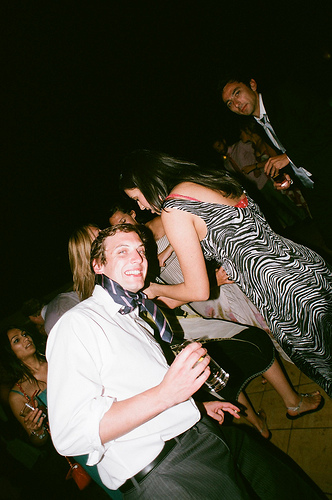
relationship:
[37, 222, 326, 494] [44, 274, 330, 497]
boy wearing suit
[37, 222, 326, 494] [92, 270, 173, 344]
boy wearing tie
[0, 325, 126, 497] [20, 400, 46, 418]
girl holding cocktail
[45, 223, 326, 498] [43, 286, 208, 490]
boy wearing shirt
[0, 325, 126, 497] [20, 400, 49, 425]
girl holding cocktail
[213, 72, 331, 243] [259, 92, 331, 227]
man wearing suit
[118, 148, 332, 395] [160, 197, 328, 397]
girl wearing dress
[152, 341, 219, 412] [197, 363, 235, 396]
hand holding glass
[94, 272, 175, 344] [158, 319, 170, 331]
tie with stripes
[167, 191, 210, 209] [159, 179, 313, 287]
bra displayed by woman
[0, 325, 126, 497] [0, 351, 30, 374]
girl with hair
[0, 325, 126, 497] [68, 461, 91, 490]
girl with bag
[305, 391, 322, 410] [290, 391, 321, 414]
foot in sandal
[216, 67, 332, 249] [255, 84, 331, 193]
man wears suit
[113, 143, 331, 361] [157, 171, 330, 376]
girl wears dress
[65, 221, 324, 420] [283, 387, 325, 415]
girl wears sandals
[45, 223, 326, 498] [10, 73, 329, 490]
boy in crowd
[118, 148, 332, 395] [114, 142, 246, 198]
girl has hair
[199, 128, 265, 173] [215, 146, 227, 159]
man has beard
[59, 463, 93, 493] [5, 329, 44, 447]
bag with woman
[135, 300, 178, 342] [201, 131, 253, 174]
tie on man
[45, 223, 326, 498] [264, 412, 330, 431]
boy on floor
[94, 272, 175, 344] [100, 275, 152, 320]
tie around neck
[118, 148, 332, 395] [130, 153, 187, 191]
girl has hair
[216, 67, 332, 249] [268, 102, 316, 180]
man wearing suit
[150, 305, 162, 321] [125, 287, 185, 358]
stripes on tie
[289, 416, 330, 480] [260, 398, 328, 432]
tiles on floor